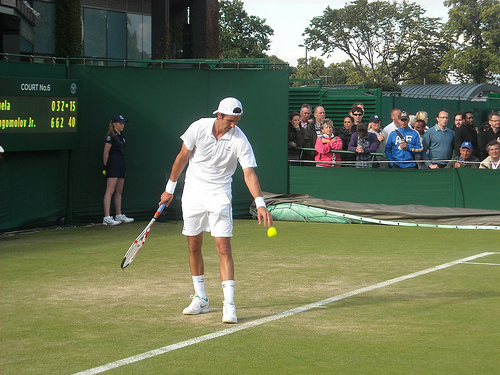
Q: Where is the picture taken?
A: At a tennis match.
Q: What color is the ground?
A: Green.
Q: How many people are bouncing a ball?
A: One.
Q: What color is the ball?
A: Yellow.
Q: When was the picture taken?
A: During the day.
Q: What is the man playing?
A: Tennis.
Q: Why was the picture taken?
A: To capture the man playing tennis.